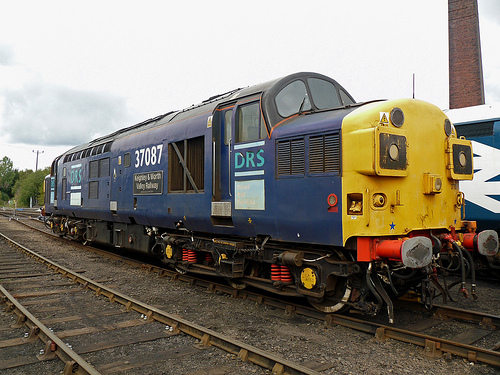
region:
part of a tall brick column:
[443, 0, 490, 118]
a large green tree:
[14, 165, 49, 203]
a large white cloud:
[5, 78, 118, 143]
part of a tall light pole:
[32, 145, 47, 167]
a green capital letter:
[232, 149, 245, 171]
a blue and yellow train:
[36, 71, 463, 326]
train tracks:
[3, 211, 498, 373]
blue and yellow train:
[39, 67, 477, 324]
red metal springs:
[267, 262, 291, 282]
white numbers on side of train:
[131, 142, 164, 169]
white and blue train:
[442, 100, 498, 239]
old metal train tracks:
[0, 205, 497, 372]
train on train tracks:
[45, 72, 480, 342]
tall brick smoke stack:
[442, 0, 486, 110]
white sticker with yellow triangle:
[378, 109, 392, 129]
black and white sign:
[131, 168, 165, 196]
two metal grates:
[273, 128, 340, 180]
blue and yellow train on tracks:
[37, 73, 482, 322]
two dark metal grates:
[277, 130, 339, 181]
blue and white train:
[444, 102, 497, 271]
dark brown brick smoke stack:
[447, 0, 488, 110]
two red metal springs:
[268, 259, 290, 285]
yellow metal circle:
[298, 267, 318, 290]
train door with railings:
[209, 101, 237, 205]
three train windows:
[260, 71, 355, 131]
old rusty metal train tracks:
[0, 205, 495, 371]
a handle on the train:
[203, 145, 222, 180]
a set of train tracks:
[44, 261, 175, 367]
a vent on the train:
[286, 137, 327, 178]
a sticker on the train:
[376, 109, 393, 125]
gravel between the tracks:
[264, 304, 319, 362]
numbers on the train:
[135, 147, 171, 172]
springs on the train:
[270, 256, 296, 288]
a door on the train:
[220, 109, 240, 149]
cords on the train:
[361, 257, 418, 310]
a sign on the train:
[230, 137, 276, 204]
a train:
[119, 73, 459, 238]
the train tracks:
[72, 305, 181, 369]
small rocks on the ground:
[288, 329, 378, 366]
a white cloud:
[28, 93, 95, 131]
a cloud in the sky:
[10, 96, 88, 139]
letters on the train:
[232, 142, 264, 172]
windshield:
[281, 88, 311, 111]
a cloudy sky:
[30, 90, 92, 130]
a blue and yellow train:
[187, 95, 453, 237]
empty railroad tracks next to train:
[2, 223, 337, 371]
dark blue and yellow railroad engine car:
[41, 65, 481, 329]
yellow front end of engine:
[343, 95, 478, 247]